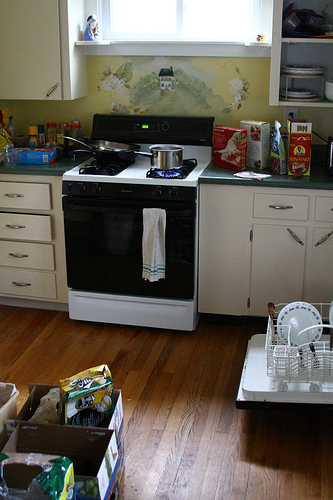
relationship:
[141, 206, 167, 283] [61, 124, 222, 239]
towel hanging in front of stove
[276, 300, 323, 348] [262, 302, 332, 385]
plate in dishwasher rack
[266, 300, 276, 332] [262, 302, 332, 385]
spoon in dishwasher rack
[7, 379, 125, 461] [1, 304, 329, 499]
box sitting on floor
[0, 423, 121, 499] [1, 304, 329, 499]
box sitting on floor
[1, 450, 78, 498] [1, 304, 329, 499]
box sitting on floor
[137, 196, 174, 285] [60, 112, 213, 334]
towel hanging on oven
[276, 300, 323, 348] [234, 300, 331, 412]
plate in dishwasher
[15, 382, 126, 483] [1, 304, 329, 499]
box on floor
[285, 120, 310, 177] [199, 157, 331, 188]
box on counter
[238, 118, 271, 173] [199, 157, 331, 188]
box on counter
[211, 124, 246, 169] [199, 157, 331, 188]
box on counter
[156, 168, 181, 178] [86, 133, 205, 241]
flame on stove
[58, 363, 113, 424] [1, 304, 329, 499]
box on floor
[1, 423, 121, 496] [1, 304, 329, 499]
box on floor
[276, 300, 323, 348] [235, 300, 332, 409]
plate in dish washer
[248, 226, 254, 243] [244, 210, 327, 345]
hinge on door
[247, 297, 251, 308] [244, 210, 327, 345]
hinge on door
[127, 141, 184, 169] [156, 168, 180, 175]
pot above flame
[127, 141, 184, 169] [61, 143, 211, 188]
pot on stove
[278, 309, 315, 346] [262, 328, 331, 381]
plate sitting in dishwasher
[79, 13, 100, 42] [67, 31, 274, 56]
figurine sitting on window ledge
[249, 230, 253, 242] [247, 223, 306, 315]
hinge on door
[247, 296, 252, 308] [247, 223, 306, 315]
hinge on door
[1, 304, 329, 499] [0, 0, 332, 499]
floor in kitchen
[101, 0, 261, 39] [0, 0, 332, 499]
window in kitchen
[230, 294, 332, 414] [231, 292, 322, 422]
dish washer on door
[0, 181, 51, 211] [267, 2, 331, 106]
drawer on cabinet